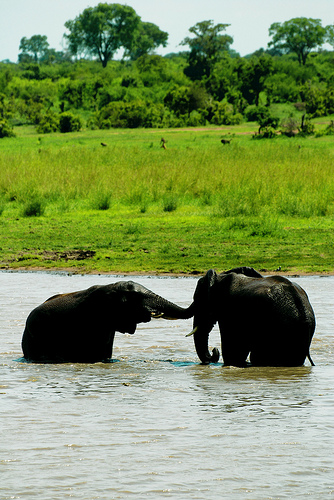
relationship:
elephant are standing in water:
[17, 276, 196, 371] [3, 270, 333, 500]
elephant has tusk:
[187, 267, 321, 369] [186, 325, 196, 337]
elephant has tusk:
[20, 279, 192, 364] [150, 309, 164, 319]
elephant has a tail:
[187, 267, 321, 369] [306, 349, 316, 368]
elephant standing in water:
[20, 279, 192, 364] [3, 270, 333, 500]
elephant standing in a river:
[187, 267, 321, 369] [3, 266, 333, 500]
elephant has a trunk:
[187, 267, 321, 369] [194, 315, 220, 366]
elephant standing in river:
[187, 267, 321, 369] [3, 266, 333, 500]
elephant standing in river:
[20, 279, 192, 364] [3, 266, 333, 500]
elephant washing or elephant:
[20, 279, 192, 364] [187, 267, 321, 369]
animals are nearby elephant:
[99, 134, 235, 152] [17, 276, 196, 371]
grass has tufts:
[4, 125, 334, 277] [25, 194, 181, 215]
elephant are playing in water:
[17, 276, 196, 371] [3, 270, 333, 500]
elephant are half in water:
[17, 276, 196, 371] [3, 270, 333, 500]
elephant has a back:
[187, 267, 321, 369] [229, 268, 298, 292]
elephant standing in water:
[187, 267, 321, 369] [3, 270, 333, 500]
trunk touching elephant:
[152, 292, 196, 321] [187, 267, 321, 369]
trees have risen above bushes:
[3, 2, 334, 99] [2, 91, 334, 138]